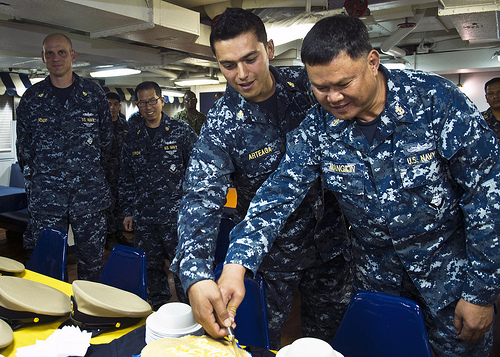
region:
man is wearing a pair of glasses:
[131, 90, 165, 109]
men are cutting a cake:
[175, 274, 258, 346]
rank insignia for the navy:
[388, 100, 413, 117]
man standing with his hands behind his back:
[18, 28, 110, 215]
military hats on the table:
[9, 259, 139, 338]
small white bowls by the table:
[138, 290, 198, 337]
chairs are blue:
[31, 220, 151, 287]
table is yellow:
[26, 267, 58, 284]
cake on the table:
[138, 332, 243, 355]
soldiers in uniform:
[16, 17, 493, 349]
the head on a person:
[41, 36, 71, 73]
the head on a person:
[103, 91, 120, 118]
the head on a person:
[133, 81, 160, 119]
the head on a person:
[182, 88, 197, 111]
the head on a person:
[210, 8, 276, 99]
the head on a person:
[299, 15, 384, 122]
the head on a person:
[482, 78, 498, 109]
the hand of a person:
[188, 276, 230, 340]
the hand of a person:
[212, 262, 246, 323]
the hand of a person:
[453, 297, 491, 338]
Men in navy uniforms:
[13, 5, 496, 354]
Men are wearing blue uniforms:
[6, 62, 499, 355]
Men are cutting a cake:
[135, 275, 280, 355]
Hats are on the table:
[0, 250, 155, 351]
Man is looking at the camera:
[11, 25, 111, 283]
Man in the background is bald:
[6, 28, 117, 280]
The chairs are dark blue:
[4, 212, 454, 355]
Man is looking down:
[283, 10, 396, 126]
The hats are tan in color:
[1, 239, 156, 354]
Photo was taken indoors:
[4, 0, 494, 355]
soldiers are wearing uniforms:
[172, 95, 488, 339]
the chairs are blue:
[15, 225, 416, 354]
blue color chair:
[107, 247, 143, 283]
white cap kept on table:
[68, 279, 146, 326]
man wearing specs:
[135, 98, 161, 106]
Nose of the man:
[327, 91, 342, 103]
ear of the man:
[368, 49, 379, 74]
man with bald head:
[41, 33, 76, 75]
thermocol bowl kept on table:
[147, 302, 191, 337]